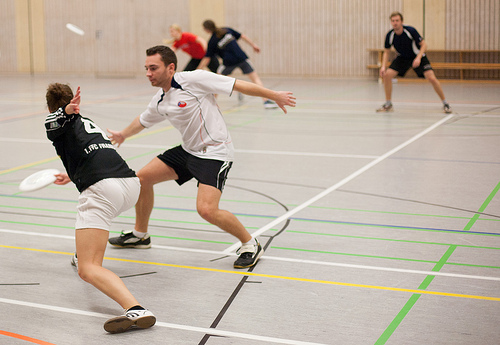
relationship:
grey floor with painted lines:
[5, 77, 499, 344] [7, 98, 498, 343]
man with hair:
[93, 40, 272, 245] [143, 44, 178, 74]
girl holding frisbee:
[38, 80, 161, 333] [18, 160, 58, 194]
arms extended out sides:
[117, 89, 314, 136] [144, 127, 233, 181]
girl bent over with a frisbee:
[44, 83, 156, 333] [17, 165, 64, 195]